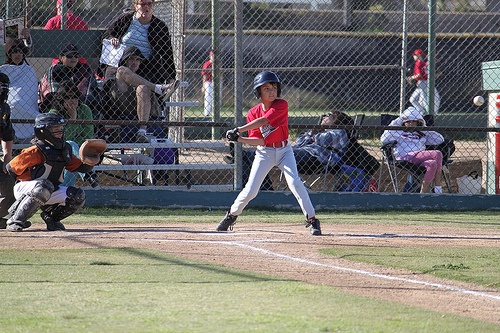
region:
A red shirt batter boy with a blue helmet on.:
[214, 67, 322, 236]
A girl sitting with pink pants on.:
[380, 105, 445, 196]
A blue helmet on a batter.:
[250, 68, 282, 94]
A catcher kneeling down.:
[4, 111, 106, 231]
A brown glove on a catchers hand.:
[75, 138, 108, 167]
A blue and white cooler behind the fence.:
[145, 134, 176, 170]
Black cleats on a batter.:
[213, 211, 323, 238]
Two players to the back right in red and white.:
[409, 48, 441, 115]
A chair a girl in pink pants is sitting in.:
[380, 113, 457, 190]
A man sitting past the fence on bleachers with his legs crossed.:
[100, 46, 180, 139]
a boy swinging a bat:
[210, 59, 326, 244]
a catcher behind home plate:
[8, 106, 110, 244]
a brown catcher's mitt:
[74, 131, 109, 166]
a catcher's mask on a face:
[44, 110, 69, 150]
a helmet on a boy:
[250, 66, 295, 101]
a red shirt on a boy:
[238, 96, 298, 146]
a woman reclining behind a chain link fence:
[224, 95, 379, 177]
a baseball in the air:
[470, 91, 488, 112]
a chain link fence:
[4, 1, 498, 195]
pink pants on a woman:
[394, 140, 450, 189]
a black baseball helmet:
[246, 68, 285, 88]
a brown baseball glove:
[75, 138, 114, 165]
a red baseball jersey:
[244, 98, 291, 143]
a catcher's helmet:
[35, 110, 71, 145]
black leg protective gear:
[10, 179, 52, 223]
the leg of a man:
[118, 66, 178, 103]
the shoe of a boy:
[305, 219, 327, 237]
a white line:
[226, 236, 498, 309]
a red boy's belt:
[258, 139, 290, 146]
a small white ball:
[472, 91, 484, 108]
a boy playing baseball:
[210, 73, 325, 238]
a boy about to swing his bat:
[217, 67, 324, 235]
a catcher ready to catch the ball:
[7, 109, 104, 229]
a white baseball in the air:
[471, 96, 486, 105]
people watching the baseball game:
[0, 1, 454, 190]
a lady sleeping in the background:
[231, 111, 354, 191]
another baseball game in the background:
[186, 48, 448, 114]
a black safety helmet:
[251, 71, 283, 102]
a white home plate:
[196, 225, 256, 239]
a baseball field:
[1, 208, 496, 328]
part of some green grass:
[199, 292, 243, 331]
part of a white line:
[368, 249, 418, 296]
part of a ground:
[244, 241, 276, 268]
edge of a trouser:
[283, 167, 300, 189]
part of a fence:
[199, 150, 216, 169]